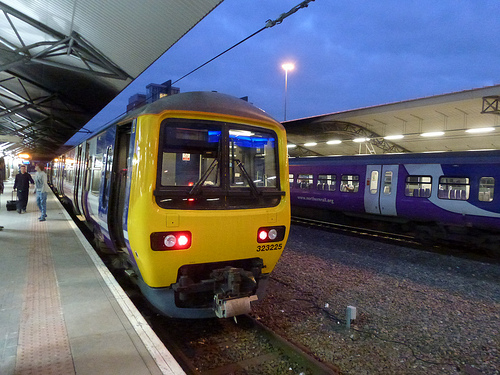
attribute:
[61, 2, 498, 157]
sky — blue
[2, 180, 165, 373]
platform — station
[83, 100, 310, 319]
train — yellow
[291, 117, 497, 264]
cars — dark blue, light blue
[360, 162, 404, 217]
door — white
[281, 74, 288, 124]
pole — tall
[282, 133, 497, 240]
train — blue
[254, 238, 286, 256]
number — black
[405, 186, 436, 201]
seat — blue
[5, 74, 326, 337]
train — modern